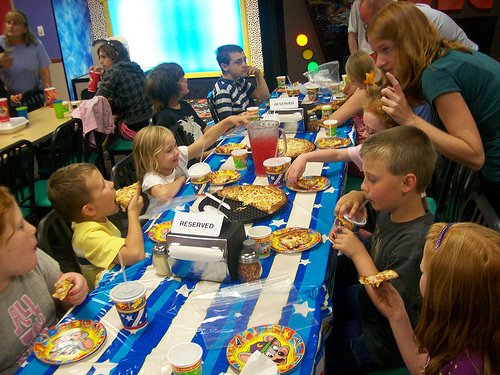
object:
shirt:
[71, 216, 127, 291]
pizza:
[114, 181, 141, 213]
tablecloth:
[0, 82, 355, 375]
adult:
[365, 0, 499, 192]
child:
[130, 107, 262, 206]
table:
[12, 83, 357, 375]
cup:
[262, 157, 286, 190]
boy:
[212, 44, 271, 121]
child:
[357, 220, 500, 375]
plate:
[225, 324, 306, 374]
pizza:
[358, 270, 398, 291]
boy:
[45, 162, 145, 293]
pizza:
[216, 184, 287, 215]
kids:
[0, 186, 91, 375]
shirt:
[368, 211, 437, 330]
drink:
[249, 137, 279, 175]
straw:
[46, 83, 50, 88]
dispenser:
[166, 222, 248, 284]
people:
[0, 11, 55, 118]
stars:
[89, 355, 119, 375]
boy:
[332, 124, 439, 318]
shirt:
[211, 74, 256, 121]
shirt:
[417, 47, 500, 137]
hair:
[358, 124, 439, 194]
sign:
[171, 212, 232, 237]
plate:
[270, 227, 322, 254]